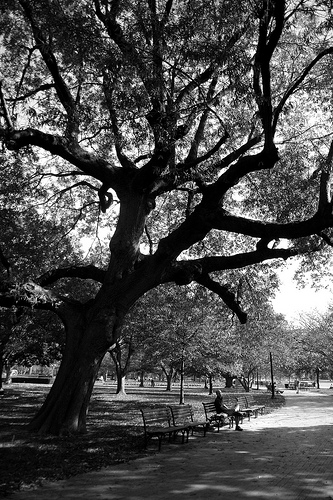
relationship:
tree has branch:
[71, 85, 316, 292] [249, 89, 323, 152]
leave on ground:
[3, 436, 120, 486] [76, 369, 318, 500]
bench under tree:
[121, 391, 215, 457] [71, 85, 316, 292]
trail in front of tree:
[244, 367, 303, 463] [71, 85, 316, 292]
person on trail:
[278, 351, 314, 399] [244, 367, 303, 463]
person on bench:
[278, 351, 314, 399] [121, 391, 215, 457]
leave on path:
[3, 436, 120, 486] [59, 446, 143, 493]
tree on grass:
[71, 85, 316, 292] [107, 391, 144, 449]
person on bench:
[214, 389, 243, 431] [121, 391, 215, 457]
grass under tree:
[107, 391, 144, 449] [71, 85, 316, 292]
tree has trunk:
[71, 85, 316, 292] [35, 323, 115, 424]